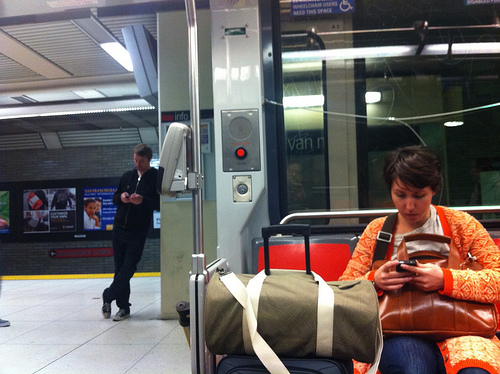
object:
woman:
[336, 143, 498, 374]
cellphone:
[394, 258, 417, 279]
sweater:
[336, 204, 499, 372]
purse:
[373, 232, 497, 338]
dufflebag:
[204, 268, 387, 373]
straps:
[310, 270, 336, 358]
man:
[102, 143, 163, 323]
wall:
[154, 10, 219, 321]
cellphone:
[124, 191, 132, 200]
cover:
[220, 107, 261, 172]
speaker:
[228, 115, 253, 139]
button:
[234, 148, 246, 159]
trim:
[234, 146, 247, 160]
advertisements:
[21, 209, 50, 235]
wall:
[1, 142, 160, 275]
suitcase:
[214, 351, 350, 373]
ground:
[0, 275, 190, 373]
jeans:
[377, 335, 489, 373]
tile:
[34, 344, 153, 373]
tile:
[0, 318, 116, 345]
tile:
[86, 317, 178, 344]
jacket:
[112, 167, 161, 230]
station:
[0, 0, 498, 373]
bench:
[190, 205, 500, 373]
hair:
[383, 143, 441, 194]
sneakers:
[111, 306, 133, 322]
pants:
[102, 223, 147, 309]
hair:
[134, 142, 153, 164]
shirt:
[390, 203, 450, 260]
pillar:
[206, 1, 269, 278]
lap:
[379, 336, 439, 374]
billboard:
[81, 186, 123, 231]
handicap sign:
[290, 0, 357, 18]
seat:
[250, 233, 357, 287]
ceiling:
[0, 0, 159, 107]